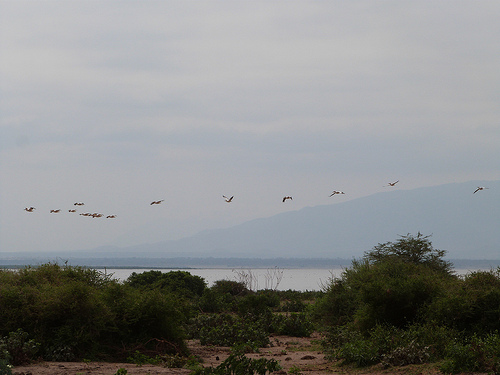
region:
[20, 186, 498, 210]
migrating birds in a line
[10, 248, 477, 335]
shrub lined shore line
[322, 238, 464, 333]
green bush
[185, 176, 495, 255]
blue mountains in hazy distance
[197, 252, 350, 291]
calm lake waters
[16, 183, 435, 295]
birds flying over a lake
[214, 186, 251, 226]
bird flying with its wings up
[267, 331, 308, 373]
wet sand and rocks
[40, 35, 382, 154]
gray cloudy skies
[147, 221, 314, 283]
shore line and rising mountains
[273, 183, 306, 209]
Bird in the sky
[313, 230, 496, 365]
Green vegetation along shore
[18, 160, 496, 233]
Line of birds flying in the sky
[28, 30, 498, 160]
Skies with nothing in them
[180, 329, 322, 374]
Dirt patch between shrubs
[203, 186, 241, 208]
Bird with wings raised up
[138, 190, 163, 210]
Bird with horizontal wings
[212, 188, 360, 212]
Three birds flying in the sky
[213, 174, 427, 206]
Four birds flying in the sky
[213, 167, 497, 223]
Five birds in a line in the sky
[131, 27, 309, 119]
this is the sky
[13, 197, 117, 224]
these are the birds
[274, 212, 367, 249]
this is a mountain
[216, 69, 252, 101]
these are the clouds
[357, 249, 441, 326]
this is a tree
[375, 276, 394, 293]
the tree has green leaves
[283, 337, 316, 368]
this is the ground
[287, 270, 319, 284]
this is a lake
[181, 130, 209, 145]
the sky is blue in color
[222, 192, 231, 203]
the bird is white in color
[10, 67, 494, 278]
the sky is hazy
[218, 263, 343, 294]
the water is gray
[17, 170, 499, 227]
the birds are flying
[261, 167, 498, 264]
you can see hills through the haze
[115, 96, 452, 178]
the sky has some clouds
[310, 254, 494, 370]
the bushes are green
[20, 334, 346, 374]
the dirt looks sandy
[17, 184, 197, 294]
the birds are over water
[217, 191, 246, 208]
the bird has wings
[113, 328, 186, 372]
tree limbs are brown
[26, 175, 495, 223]
birds flying in a flock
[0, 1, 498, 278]
overcast misty grey sky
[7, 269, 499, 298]
large calm inland lake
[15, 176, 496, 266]
mountain or high hilly area on far side of lake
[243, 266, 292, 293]
bush with no leafs on shore of lake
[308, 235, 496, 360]
area of bushy plant growth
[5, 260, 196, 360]
area of low bushy growth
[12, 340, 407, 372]
area of hardpan earth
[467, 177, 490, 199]
bird flying at end of line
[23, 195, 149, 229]
v shaped formation of flying birds